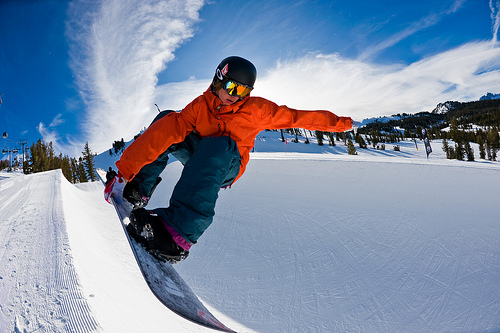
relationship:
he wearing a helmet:
[125, 56, 359, 262] [213, 56, 255, 89]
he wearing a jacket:
[95, 50, 359, 278] [112, 84, 354, 190]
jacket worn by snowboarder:
[112, 84, 354, 190] [103, 55, 366, 264]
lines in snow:
[38, 189, 94, 331] [12, 174, 147, 330]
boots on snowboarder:
[122, 203, 189, 285] [99, 31, 370, 279]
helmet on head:
[213, 54, 258, 90] [205, 51, 261, 113]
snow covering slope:
[2, 132, 495, 331] [1, 127, 499, 332]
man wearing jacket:
[112, 46, 329, 266] [112, 80, 354, 199]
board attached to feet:
[92, 167, 238, 332] [121, 180, 192, 263]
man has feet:
[102, 55, 364, 262] [121, 180, 192, 263]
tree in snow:
[45, 138, 57, 170] [2, 132, 495, 331]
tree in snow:
[80, 141, 96, 177] [2, 132, 495, 331]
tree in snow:
[68, 156, 79, 184] [2, 132, 495, 331]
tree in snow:
[32, 138, 46, 169] [2, 132, 495, 331]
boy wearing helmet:
[111, 56, 360, 246] [202, 49, 271, 89]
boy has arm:
[114, 53, 360, 264] [264, 100, 366, 135]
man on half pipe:
[92, 36, 398, 277] [0, 154, 500, 331]